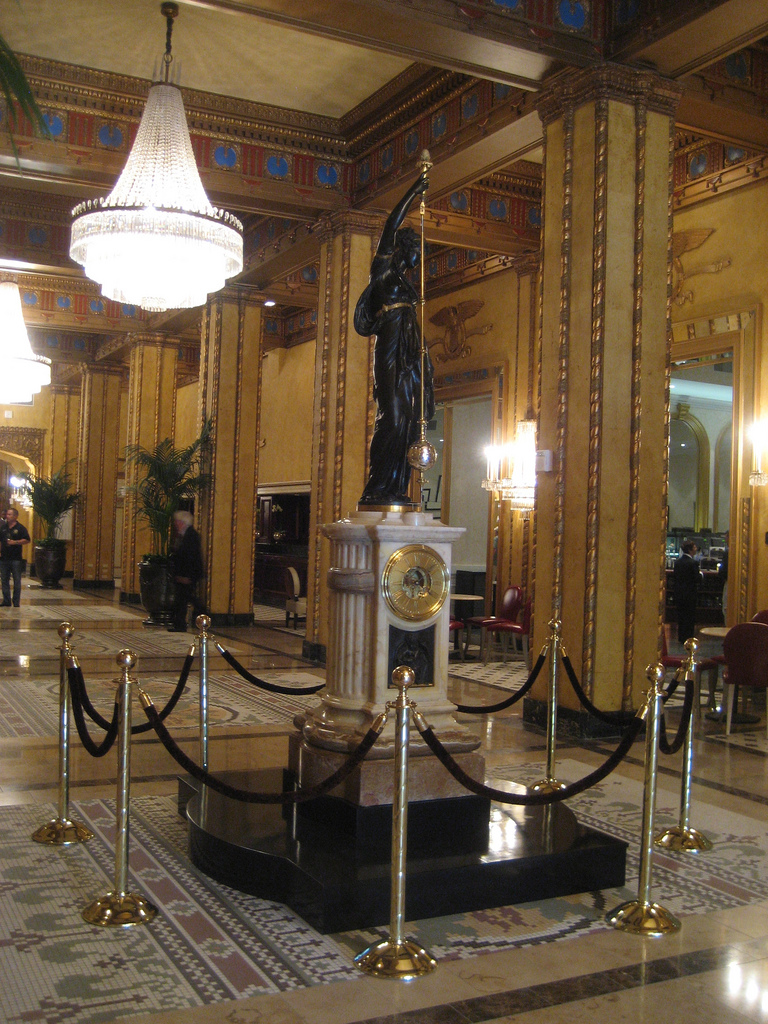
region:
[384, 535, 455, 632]
round gold colored clock in center of statue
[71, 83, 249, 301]
white crystal chandelier hanging from ceiling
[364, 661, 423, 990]
golden ball ontop of post and half circle base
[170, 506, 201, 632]
grey haired older man leaning against wall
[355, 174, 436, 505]
dark colored statue of woman with outstretched arm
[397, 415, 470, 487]
golden globe suspended on golden rod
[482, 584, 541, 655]
two red chairs next two the wall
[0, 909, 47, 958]
brown decorated design in tile floor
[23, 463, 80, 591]
green palm like tree in a brown pot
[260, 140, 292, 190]
blue circular design at top of wall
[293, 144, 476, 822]
black statue on marble base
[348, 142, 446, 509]
black statue holding golden rod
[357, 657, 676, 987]
golden post with black rope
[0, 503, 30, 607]
man wearing black shirt standing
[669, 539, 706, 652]
man in black suit standing at counter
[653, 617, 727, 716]
red chair at wood table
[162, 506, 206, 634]
grey haired man in black suit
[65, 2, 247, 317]
large glass chandelier hanging from ceiling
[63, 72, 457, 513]
large glass chandelier beside glass statue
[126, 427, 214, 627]
man in suit standing by plant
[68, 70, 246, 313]
Large fancy diamond chandelier.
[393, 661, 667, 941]
Black rope hanging from gold posts.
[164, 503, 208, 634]
Man walking through lobby.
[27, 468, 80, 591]
Very tall potted plant.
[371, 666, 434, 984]
Gold post for holding rope.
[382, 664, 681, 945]
Rope to protect statue.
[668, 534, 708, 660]
Man wearing black suit.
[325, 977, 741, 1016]
Marble flooring in lobby.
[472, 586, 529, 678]
Red chair in lobby.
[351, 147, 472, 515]
Large black statue on pedestal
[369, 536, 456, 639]
Clock on pedestal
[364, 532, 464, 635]
Clock with a golden face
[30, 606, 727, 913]
Ropes surrounding statue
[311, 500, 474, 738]
Clock on front of the pedestal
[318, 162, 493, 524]
Statue is very tall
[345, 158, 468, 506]
Statue on top of clock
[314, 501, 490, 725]
White column underneath statue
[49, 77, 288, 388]
Large chandelier near statue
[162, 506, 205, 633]
a gray haired man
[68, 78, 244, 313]
a large chandelier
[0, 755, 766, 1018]
a large rectangular rug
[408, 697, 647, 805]
black rope with metal ends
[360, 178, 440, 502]
The black statue on the stand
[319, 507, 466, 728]
The white stand holding the statue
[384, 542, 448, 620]
The gold clock on the stand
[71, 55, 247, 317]
The chandelier hanging over the statue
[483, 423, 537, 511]
The lights on the wall behind the pillar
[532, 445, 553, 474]
The white meter on the wall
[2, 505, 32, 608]
The man in the large room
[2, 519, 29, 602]
The black clothes on the person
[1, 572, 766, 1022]
The floor of the room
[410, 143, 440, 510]
The staff int he hand of the statue